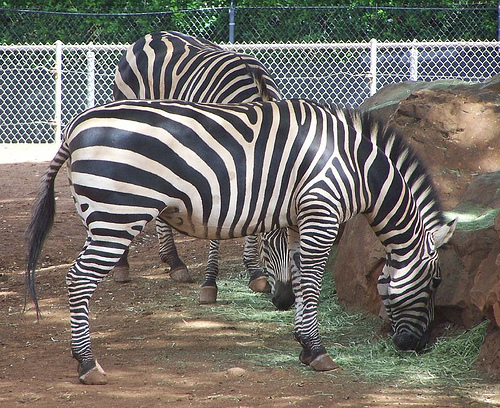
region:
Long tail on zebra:
[16, 127, 69, 322]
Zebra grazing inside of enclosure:
[21, 97, 460, 382]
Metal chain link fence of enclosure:
[1, 40, 498, 157]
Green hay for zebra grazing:
[210, 265, 499, 381]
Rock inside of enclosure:
[330, 65, 495, 375]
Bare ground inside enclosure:
[7, 240, 245, 402]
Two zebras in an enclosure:
[11, 39, 459, 384]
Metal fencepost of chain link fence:
[49, 38, 64, 163]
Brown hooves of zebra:
[111, 261, 269, 305]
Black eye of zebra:
[424, 274, 443, 292]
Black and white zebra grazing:
[20, 98, 464, 385]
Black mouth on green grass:
[390, 320, 433, 349]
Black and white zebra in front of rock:
[20, 95, 459, 385]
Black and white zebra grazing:
[110, 29, 295, 313]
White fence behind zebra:
[0, 40, 499, 152]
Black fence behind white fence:
[0, 8, 498, 45]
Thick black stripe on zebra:
[69, 123, 214, 241]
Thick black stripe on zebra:
[107, 97, 254, 240]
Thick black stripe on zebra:
[239, 97, 272, 244]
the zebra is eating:
[382, 175, 471, 398]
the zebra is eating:
[233, 197, 320, 354]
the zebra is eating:
[371, 235, 448, 385]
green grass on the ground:
[339, 330, 434, 400]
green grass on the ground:
[220, 258, 287, 348]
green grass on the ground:
[299, 268, 377, 368]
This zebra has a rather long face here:
[381, 247, 460, 366]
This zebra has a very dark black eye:
[427, 270, 443, 294]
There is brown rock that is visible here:
[447, 95, 477, 156]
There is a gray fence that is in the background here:
[14, 37, 48, 99]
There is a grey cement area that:
[6, 143, 18, 155]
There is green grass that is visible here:
[261, 303, 276, 325]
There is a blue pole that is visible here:
[223, 14, 238, 38]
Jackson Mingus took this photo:
[74, 74, 394, 372]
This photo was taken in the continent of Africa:
[72, 63, 435, 384]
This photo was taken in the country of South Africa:
[65, 53, 409, 359]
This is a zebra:
[18, 88, 494, 402]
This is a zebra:
[91, 15, 321, 340]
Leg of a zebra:
[300, 208, 355, 375]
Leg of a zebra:
[279, 196, 300, 388]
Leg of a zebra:
[243, 196, 275, 333]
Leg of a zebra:
[195, 223, 229, 329]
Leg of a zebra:
[147, 197, 197, 300]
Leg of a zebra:
[112, 239, 141, 305]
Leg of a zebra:
[61, 205, 121, 400]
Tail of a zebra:
[6, 125, 65, 362]